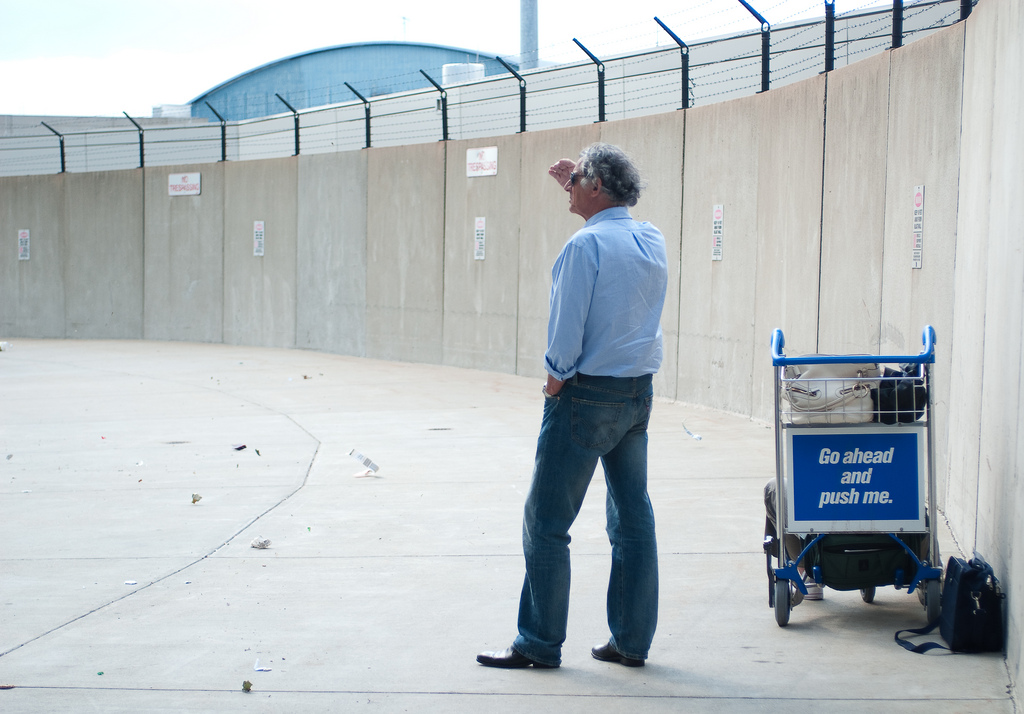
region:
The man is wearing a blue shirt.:
[476, 138, 717, 670]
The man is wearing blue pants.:
[486, 141, 682, 677]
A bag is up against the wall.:
[900, 557, 1017, 674]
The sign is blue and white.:
[781, 424, 941, 532]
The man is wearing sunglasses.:
[536, 141, 654, 249]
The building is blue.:
[155, 0, 539, 125]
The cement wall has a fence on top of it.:
[2, 0, 1004, 425]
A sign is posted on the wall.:
[155, 165, 220, 208]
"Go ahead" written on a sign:
[801, 430, 915, 475]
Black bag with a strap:
[882, 539, 1012, 660]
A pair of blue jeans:
[498, 364, 670, 663]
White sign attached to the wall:
[149, 156, 216, 205]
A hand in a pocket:
[522, 351, 576, 427]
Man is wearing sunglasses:
[547, 136, 652, 228]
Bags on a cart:
[748, 314, 955, 637]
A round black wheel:
[753, 569, 802, 639]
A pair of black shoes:
[466, 631, 654, 680]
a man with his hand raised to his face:
[541, 146, 590, 211]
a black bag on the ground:
[927, 541, 1020, 663]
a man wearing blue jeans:
[510, 358, 669, 668]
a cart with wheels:
[769, 324, 954, 637]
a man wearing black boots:
[472, 630, 568, 669]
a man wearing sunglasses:
[561, 150, 597, 193]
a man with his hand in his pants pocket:
[538, 374, 561, 404]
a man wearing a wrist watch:
[531, 370, 567, 405]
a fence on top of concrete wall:
[16, 121, 298, 173]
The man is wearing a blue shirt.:
[555, 222, 683, 381]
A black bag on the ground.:
[928, 543, 1004, 645]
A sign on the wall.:
[448, 140, 505, 182]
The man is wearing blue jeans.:
[534, 389, 667, 630]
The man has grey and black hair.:
[590, 145, 632, 185]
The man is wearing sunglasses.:
[549, 159, 594, 194]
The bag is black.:
[945, 550, 1004, 645]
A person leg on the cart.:
[754, 477, 825, 613]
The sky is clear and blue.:
[32, 4, 349, 74]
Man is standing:
[473, 138, 673, 671]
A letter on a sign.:
[817, 444, 833, 471]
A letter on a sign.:
[843, 469, 851, 482]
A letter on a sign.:
[859, 462, 870, 485]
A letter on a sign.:
[830, 447, 841, 470]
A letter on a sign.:
[844, 446, 852, 463]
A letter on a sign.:
[862, 449, 870, 463]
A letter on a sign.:
[875, 450, 883, 461]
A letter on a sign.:
[885, 443, 895, 466]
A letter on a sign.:
[862, 463, 872, 480]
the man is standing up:
[472, 141, 668, 673]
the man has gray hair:
[476, 143, 666, 669]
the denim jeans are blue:
[512, 370, 659, 669]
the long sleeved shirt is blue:
[542, 203, 667, 381]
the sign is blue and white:
[781, 420, 927, 537]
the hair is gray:
[576, 138, 647, 208]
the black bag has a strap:
[892, 546, 1011, 660]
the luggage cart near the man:
[473, 141, 936, 677]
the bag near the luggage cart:
[765, 322, 1007, 656]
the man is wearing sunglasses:
[473, 143, 666, 676]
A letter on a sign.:
[818, 443, 832, 467]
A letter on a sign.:
[831, 449, 841, 465]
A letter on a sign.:
[841, 452, 851, 465]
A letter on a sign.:
[850, 446, 861, 466]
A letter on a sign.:
[874, 447, 882, 461]